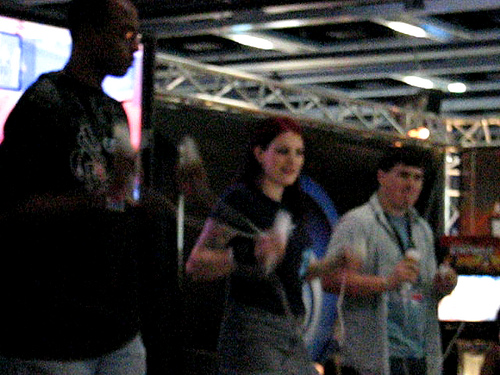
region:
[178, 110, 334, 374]
Lady in a black sleeveless top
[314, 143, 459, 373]
Man in an unbuttoned shirt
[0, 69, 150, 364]
Man wearing a black shirt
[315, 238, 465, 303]
Pair of hands on the front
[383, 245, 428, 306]
Hand holding a white topped object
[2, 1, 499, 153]
Roof reinforced with steel structures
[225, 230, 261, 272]
Band on the wrist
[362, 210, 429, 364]
Blue round necked inner shirt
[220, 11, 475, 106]
Lightings on the roof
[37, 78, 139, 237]
Brandings on a shirt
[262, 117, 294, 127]
this is the hair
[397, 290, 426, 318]
this is the stomach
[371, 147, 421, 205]
this is the head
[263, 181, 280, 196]
this is the neck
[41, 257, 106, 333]
the shirt is black in colour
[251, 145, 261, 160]
this is the ear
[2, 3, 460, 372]
three people standing next to each other playing video games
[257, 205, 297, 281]
white video game controller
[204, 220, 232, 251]
tattoo on upper arm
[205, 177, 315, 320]
black short sleeve shirt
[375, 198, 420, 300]
black ribbon around neck with badge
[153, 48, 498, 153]
metal railing near ceiling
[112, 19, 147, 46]
pair of eye glasses on man's face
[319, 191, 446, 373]
open short sleeve collared shirt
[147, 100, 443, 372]
black tarp wall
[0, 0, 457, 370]
the three people standing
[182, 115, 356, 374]
the woman standing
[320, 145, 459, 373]
the man on the far right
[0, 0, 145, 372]
the man on the far left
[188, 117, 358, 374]
the person in the middle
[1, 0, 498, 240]
the metal frame of the enclosure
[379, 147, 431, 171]
the hair on the man's head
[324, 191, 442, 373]
the shirt on the man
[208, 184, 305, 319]
the shirt on the woman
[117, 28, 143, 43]
the glasses on the man's face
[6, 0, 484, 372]
a group of three people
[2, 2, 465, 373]
people playing wii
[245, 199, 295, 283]
Wii controller in the hand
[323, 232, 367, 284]
Wii nunchuck in the hand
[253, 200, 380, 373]
white cord connecting the controller to the nunchuck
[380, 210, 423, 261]
black lanyard around the neck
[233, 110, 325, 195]
dark red hair on the head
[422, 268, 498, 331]
black monitor is lit up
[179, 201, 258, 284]
arm is bent at the elbow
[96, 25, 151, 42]
glasses on the face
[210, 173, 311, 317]
shirt worn by woman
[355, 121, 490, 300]
a person playing a wii remote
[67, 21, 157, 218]
a person playing a wii remote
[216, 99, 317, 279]
a person holding a wii remote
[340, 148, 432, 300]
a person standing inside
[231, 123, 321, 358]
a person standing inside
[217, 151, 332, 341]
a person wearing a shirt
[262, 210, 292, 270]
a white wii controller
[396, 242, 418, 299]
a white wii controller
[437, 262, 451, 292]
a white wii controller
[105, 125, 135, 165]
a white wii controller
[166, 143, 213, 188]
a white wii controller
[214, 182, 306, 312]
a black tee shirt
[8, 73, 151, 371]
a black tee shirt